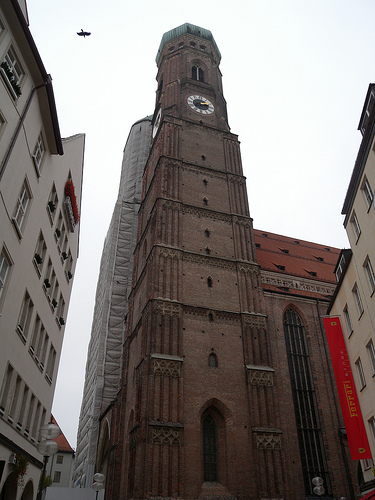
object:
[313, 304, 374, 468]
flag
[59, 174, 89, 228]
flowers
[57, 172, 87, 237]
window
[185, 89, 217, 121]
clock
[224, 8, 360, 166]
sky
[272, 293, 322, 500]
window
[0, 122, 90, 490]
building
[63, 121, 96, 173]
pointy top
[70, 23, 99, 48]
bird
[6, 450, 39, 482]
bush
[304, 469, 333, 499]
round shades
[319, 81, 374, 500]
building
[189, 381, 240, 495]
window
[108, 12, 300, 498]
church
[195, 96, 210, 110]
hands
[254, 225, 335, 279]
roof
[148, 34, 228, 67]
fence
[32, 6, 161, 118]
air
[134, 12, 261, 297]
tower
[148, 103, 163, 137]
clock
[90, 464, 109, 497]
lights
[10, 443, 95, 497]
street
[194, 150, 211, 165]
window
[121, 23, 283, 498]
buildings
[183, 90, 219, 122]
roman numerals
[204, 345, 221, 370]
arch windows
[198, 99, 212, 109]
gold hand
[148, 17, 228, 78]
roof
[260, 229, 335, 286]
roof